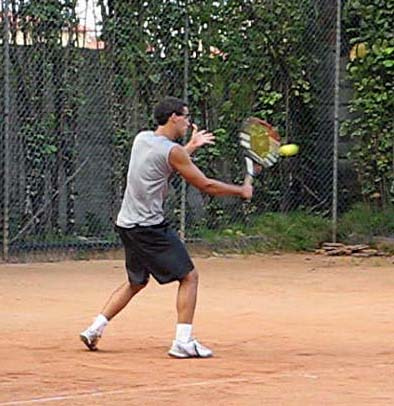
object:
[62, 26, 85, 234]
tree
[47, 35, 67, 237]
tree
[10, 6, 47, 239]
tree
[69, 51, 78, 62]
green leaves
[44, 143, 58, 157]
green leaves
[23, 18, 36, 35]
green leaves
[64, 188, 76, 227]
brown bark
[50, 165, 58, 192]
brown bark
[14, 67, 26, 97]
brown bark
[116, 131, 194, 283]
tennis outfit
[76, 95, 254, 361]
man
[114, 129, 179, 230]
grey shirt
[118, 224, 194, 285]
black shorts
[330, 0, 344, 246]
pole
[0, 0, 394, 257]
length fence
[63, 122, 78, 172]
tree trunk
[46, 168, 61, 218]
tree trunk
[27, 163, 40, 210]
tree trunk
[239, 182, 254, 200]
hand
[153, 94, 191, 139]
head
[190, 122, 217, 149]
hand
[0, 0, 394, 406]
picture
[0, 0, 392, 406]
day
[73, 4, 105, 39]
sky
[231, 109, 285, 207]
tennis racket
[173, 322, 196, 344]
socks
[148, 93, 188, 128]
hair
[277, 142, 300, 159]
ball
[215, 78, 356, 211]
air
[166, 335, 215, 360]
shoes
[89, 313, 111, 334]
socks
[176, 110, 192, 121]
eyeglasses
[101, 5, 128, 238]
trees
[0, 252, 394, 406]
clay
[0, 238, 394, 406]
court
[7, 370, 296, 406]
lines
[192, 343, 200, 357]
mark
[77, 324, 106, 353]
sneakers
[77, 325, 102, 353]
feet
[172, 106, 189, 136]
face